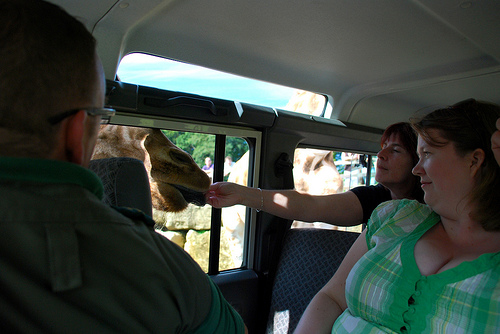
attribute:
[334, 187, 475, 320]
shirt — woman's green, white 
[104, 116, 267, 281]
window — side 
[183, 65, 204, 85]
sky — blue, cloudy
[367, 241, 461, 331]
shirt — green, white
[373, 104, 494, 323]
woman — green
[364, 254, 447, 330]
shirt — white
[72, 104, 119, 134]
eyeglasses — black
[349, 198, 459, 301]
blouse — green, white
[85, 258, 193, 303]
shirt — dark, green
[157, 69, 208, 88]
sky — cloudy, blue